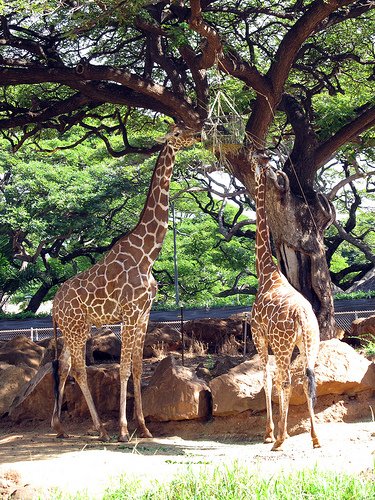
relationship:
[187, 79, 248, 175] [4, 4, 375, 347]
food in tree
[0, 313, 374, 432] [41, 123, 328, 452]
rocks behind giraffes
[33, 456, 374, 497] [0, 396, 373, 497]
grass in foreground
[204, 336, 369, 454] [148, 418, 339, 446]
rock casting shadow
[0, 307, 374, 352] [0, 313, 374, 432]
fence behind rocks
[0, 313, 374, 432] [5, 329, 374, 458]
rocks in circle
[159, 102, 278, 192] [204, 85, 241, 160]
eating from basket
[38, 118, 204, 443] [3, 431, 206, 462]
giraffe casting shadow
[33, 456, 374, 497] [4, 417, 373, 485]
grass in dirt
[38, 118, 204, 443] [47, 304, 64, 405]
giraffe has tail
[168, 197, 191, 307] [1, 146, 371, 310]
pole in background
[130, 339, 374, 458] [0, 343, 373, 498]
sun shining on ground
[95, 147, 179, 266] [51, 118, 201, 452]
neck of giraffe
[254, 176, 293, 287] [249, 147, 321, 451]
neck of giraffe